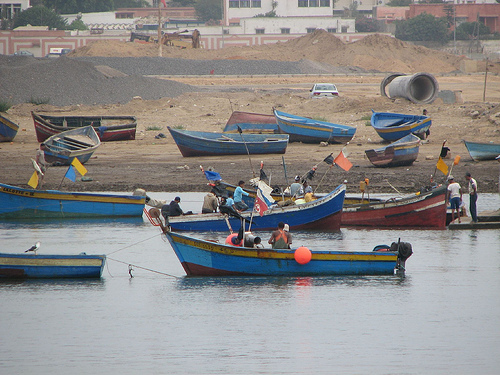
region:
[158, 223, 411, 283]
the boat is on the water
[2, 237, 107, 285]
the boat is on the water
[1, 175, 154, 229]
the boat is on the water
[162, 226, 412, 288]
the boat is blue in color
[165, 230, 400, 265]
the boat has a yellow stripe across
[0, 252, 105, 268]
the boat has a yellow stripe across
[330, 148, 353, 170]
the flag is red in color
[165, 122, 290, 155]
the boat is on the ground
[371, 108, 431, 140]
the boat is on the ground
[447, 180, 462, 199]
the shirt is white in color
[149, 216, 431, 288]
blue and yellow boat in the water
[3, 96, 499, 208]
numerous boats on the shore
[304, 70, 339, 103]
car on the road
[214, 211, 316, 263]
people in the boat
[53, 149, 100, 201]
blue and white flags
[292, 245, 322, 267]
orange circle on the side of the boat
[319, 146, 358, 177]
black and red flags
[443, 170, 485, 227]
two people standing up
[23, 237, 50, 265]
bird perched on the boat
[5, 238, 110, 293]
blue and white boat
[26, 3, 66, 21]
this is a tree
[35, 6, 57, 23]
the leaves are green in color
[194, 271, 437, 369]
this is a water body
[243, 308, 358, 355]
the water is calm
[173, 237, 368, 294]
this is a boat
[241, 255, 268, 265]
the boat is blue in color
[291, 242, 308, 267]
this is a balloon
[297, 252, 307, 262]
the balloon is red in color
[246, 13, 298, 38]
this is a building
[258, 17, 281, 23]
the wall is white in color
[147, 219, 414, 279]
a boat in the river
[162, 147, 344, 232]
people in a boat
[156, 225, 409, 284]
the boat is blue and yellow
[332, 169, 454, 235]
this boat is red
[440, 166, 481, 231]
men standing on the ramp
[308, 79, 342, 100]
a car behind the dirt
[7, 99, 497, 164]
boats sitting on the dirt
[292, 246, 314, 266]
an orange buoy on the side of the boat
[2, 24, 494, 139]
a construction site beside the river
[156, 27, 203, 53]
a tractor in the construction site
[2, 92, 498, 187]
THE BOATS ARE ON THE BEACH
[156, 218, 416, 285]
THE BOAT IS BLUE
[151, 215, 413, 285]
THIS IS A BOAT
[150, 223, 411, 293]
THE BOAT IS IN THE WATER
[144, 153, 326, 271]
THE MEN ARE ON THE BOATS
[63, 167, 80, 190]
THE FLAG IS BLUE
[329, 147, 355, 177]
THE FLAG IS ORANGE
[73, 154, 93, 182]
THE FLAG IS YELLOW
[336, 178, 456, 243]
THE BOAT IS RED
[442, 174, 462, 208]
THE PERSON IS WEARING A WHITE SHIRT